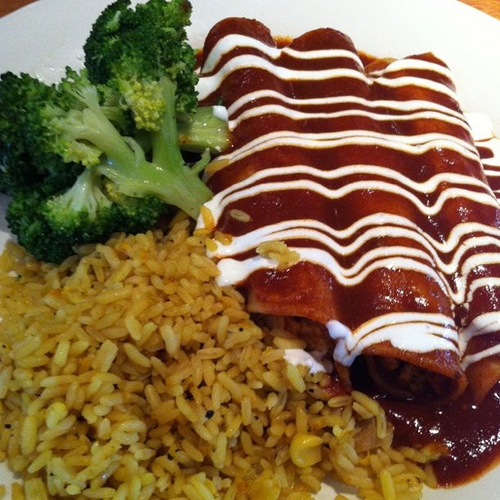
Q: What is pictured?
A: Food.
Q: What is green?
A: Broccoli.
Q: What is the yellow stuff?
A: It is rice.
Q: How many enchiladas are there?
A: 3.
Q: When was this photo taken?
A: Meal time.